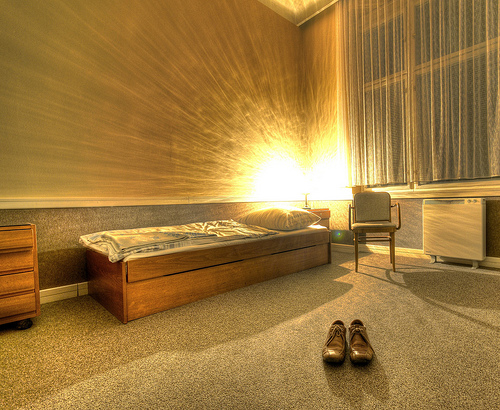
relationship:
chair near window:
[346, 189, 403, 274] [342, 0, 499, 193]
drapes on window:
[344, 0, 499, 188] [342, 0, 499, 193]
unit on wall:
[421, 195, 490, 271] [309, 193, 499, 266]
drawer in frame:
[125, 229, 334, 285] [83, 228, 334, 324]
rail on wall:
[0, 194, 309, 208] [0, 0, 304, 300]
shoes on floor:
[321, 318, 375, 366] [1, 246, 499, 406]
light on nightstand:
[264, 148, 349, 205] [305, 207, 333, 228]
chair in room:
[346, 189, 403, 274] [0, 0, 499, 409]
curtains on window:
[344, 0, 499, 188] [342, 0, 499, 193]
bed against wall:
[80, 204, 332, 324] [0, 0, 304, 300]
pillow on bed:
[237, 204, 322, 232] [80, 204, 332, 324]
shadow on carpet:
[4, 257, 354, 409] [1, 246, 499, 406]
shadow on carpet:
[357, 258, 500, 330] [1, 246, 499, 406]